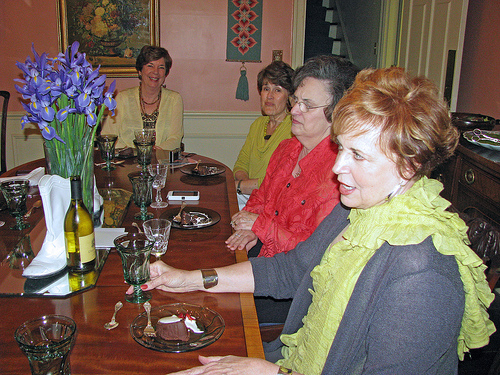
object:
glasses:
[287, 95, 332, 113]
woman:
[125, 64, 499, 374]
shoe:
[21, 173, 104, 280]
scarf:
[271, 176, 497, 375]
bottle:
[64, 175, 97, 292]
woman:
[224, 57, 364, 259]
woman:
[101, 45, 185, 156]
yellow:
[100, 86, 185, 157]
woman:
[232, 60, 296, 211]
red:
[242, 135, 340, 258]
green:
[13, 41, 117, 222]